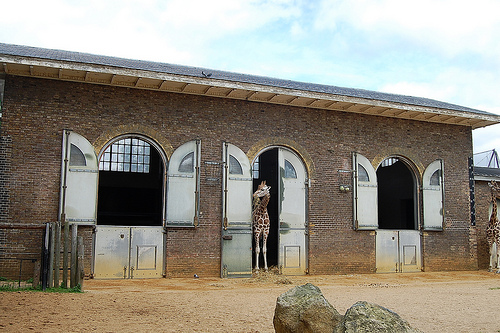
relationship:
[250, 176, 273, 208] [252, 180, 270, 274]
head of giraffe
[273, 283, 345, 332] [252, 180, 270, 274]
rock near giraffe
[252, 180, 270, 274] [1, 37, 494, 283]
giraffe in building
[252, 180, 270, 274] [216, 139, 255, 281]
giraffe looking out of door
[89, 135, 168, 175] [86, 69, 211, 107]
window in building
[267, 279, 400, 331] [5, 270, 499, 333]
rock on ground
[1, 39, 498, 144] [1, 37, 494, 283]
roof of building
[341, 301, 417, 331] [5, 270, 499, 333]
rock on ground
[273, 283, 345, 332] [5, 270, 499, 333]
rock on ground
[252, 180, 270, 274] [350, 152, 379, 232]
giraffe in door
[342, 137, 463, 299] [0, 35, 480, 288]
door of stable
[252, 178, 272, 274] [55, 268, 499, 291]
giraffe standing near door step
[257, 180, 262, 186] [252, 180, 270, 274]
horns on giraffe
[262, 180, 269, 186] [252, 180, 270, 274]
horns on giraffe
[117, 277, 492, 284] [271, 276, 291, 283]
floor made of dirt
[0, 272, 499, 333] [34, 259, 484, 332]
area made of dirt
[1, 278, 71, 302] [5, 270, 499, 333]
grass on ground